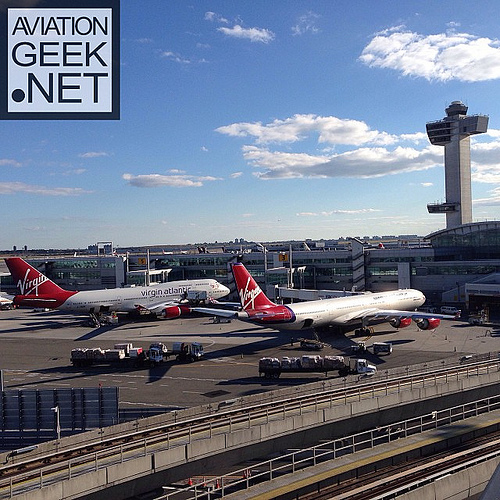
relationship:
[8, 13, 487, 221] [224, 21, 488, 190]
sky with white clouds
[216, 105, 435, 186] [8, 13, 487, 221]
cloud in sky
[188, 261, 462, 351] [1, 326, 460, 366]
airport parked on tarmac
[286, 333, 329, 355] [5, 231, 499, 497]
trolley at airport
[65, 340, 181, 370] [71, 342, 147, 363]
truck loaded with packages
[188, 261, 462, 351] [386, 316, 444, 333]
airport has jet engines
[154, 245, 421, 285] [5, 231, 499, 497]
passenger terminal at airport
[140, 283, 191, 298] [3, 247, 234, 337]
name on side of plane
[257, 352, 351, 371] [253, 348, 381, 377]
luggage loaded in cargo bay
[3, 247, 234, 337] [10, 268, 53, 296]
plane says virgin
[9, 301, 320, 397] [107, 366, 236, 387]
runway has lines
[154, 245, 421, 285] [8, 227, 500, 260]
building in back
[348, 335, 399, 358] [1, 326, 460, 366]
luggage on tarmack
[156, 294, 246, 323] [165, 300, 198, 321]
wing has red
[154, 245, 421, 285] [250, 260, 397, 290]
building has many windows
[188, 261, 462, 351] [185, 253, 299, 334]
airport has tail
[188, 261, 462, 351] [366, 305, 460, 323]
airport has wing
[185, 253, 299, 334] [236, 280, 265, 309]
tail has a word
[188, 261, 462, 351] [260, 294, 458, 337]
airport see side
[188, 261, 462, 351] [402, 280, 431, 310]
airport has nose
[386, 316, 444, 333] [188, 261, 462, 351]
engines on side of airport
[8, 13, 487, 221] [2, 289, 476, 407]
sky above land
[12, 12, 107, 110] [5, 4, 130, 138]
words are on left corner